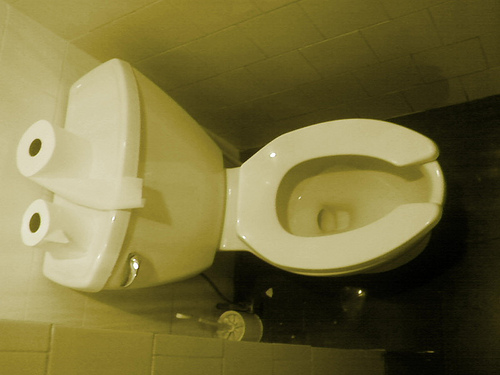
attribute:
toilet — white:
[39, 93, 455, 311]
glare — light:
[255, 151, 295, 166]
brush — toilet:
[193, 310, 261, 341]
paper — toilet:
[8, 119, 96, 201]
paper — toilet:
[18, 126, 117, 209]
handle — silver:
[121, 255, 147, 292]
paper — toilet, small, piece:
[255, 289, 285, 299]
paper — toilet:
[5, 112, 103, 251]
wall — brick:
[158, 322, 335, 372]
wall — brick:
[185, 10, 469, 146]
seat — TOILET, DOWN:
[223, 121, 436, 245]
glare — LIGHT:
[327, 281, 399, 315]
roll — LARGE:
[14, 122, 53, 169]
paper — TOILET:
[60, 162, 140, 221]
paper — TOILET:
[10, 192, 80, 269]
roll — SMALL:
[31, 214, 40, 221]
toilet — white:
[41, 49, 452, 319]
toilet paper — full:
[14, 116, 154, 216]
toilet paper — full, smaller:
[12, 196, 86, 256]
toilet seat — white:
[228, 113, 446, 273]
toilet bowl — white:
[37, 51, 451, 311]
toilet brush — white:
[168, 309, 242, 341]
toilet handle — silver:
[116, 249, 145, 294]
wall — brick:
[3, 318, 383, 373]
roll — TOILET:
[14, 116, 146, 206]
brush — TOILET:
[171, 306, 263, 342]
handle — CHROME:
[120, 251, 143, 292]